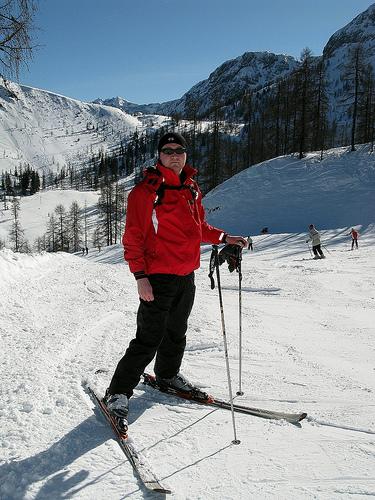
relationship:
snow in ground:
[285, 265, 350, 296] [7, 240, 110, 331]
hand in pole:
[223, 234, 249, 246] [235, 241, 244, 394]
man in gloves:
[104, 132, 248, 419] [215, 241, 240, 272]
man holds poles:
[104, 132, 248, 419] [204, 267, 270, 470]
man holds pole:
[104, 132, 248, 419] [213, 250, 283, 410]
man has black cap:
[104, 132, 248, 419] [159, 130, 189, 150]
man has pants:
[104, 132, 248, 419] [107, 270, 197, 395]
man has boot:
[104, 132, 248, 419] [154, 335, 194, 391]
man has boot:
[104, 132, 248, 419] [101, 359, 143, 421]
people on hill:
[245, 233, 254, 252] [70, 227, 373, 387]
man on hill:
[306, 224, 326, 260] [70, 227, 373, 387]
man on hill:
[346, 227, 358, 249] [70, 227, 373, 387]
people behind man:
[245, 233, 254, 252] [104, 132, 248, 419]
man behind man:
[306, 224, 326, 260] [104, 132, 248, 419]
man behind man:
[346, 227, 358, 249] [104, 132, 248, 419]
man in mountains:
[93, 100, 283, 423] [1, 0, 373, 229]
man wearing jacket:
[104, 132, 248, 419] [122, 168, 220, 275]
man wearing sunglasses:
[104, 132, 248, 419] [156, 144, 188, 156]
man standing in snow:
[104, 132, 248, 419] [0, 83, 374, 498]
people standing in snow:
[246, 235, 253, 251] [250, 251, 301, 284]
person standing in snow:
[262, 227, 267, 232] [270, 262, 353, 296]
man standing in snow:
[104, 132, 248, 419] [270, 262, 353, 296]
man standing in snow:
[346, 227, 358, 249] [0, 83, 374, 498]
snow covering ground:
[0, 83, 374, 498] [2, 244, 373, 497]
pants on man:
[94, 263, 218, 429] [125, 127, 215, 437]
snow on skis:
[0, 152, 362, 498] [78, 384, 305, 491]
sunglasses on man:
[160, 143, 191, 157] [104, 132, 248, 419]